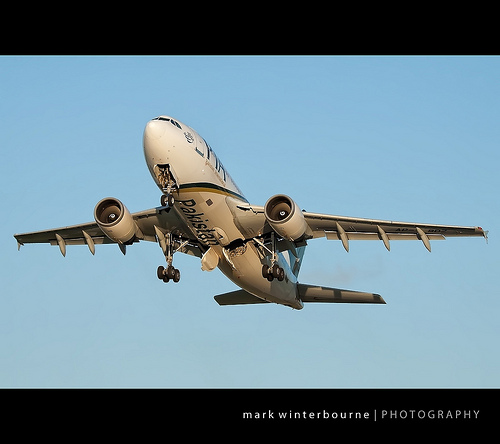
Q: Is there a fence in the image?
A: No, there are no fences.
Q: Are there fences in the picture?
A: No, there are no fences.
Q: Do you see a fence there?
A: No, there are no fences.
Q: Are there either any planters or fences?
A: No, there are no fences or planters.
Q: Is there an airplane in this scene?
A: Yes, there is an airplane.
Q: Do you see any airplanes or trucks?
A: Yes, there is an airplane.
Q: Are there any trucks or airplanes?
A: Yes, there is an airplane.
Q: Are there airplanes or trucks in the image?
A: Yes, there is an airplane.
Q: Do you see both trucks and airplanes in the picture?
A: No, there is an airplane but no trucks.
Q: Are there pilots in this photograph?
A: No, there are no pilots.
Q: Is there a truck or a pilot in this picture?
A: No, there are no pilots or trucks.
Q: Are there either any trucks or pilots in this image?
A: No, there are no pilots or trucks.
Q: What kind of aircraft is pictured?
A: The aircraft is an airplane.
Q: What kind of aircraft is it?
A: The aircraft is an airplane.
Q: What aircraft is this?
A: This is an airplane.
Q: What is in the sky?
A: The plane is in the sky.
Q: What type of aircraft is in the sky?
A: The aircraft is an airplane.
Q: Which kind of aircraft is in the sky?
A: The aircraft is an airplane.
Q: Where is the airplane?
A: The airplane is in the sky.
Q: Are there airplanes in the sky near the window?
A: Yes, there is an airplane in the sky.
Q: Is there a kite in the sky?
A: No, there is an airplane in the sky.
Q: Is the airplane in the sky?
A: Yes, the airplane is in the sky.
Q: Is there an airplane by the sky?
A: Yes, there is an airplane by the sky.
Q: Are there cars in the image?
A: No, there are no cars.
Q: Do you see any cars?
A: No, there are no cars.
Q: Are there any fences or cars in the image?
A: No, there are no cars or fences.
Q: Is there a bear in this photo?
A: No, there are no bears.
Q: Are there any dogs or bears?
A: No, there are no bears or dogs.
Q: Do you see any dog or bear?
A: No, there are no bears or dogs.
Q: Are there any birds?
A: No, there are no birds.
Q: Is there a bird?
A: No, there are no birds.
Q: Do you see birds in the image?
A: No, there are no birds.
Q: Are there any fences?
A: No, there are no fences.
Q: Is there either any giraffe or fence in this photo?
A: No, there are no fences or giraffes.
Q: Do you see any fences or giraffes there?
A: No, there are no fences or giraffes.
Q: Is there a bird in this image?
A: No, there are no birds.